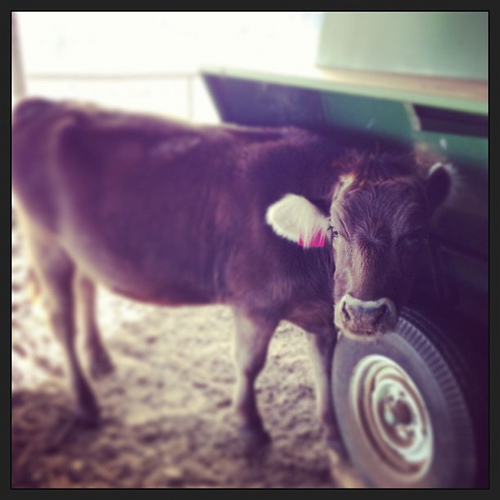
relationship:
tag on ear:
[297, 230, 326, 249] [267, 191, 333, 249]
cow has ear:
[11, 98, 455, 446] [267, 191, 333, 249]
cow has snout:
[11, 98, 455, 446] [330, 293, 399, 341]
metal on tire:
[347, 352, 434, 483] [332, 314, 489, 489]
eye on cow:
[330, 229, 340, 240] [11, 98, 455, 446]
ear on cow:
[424, 163, 459, 211] [11, 98, 455, 446]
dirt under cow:
[12, 236, 338, 489] [11, 98, 455, 446]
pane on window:
[13, 17, 25, 103] [12, 13, 320, 124]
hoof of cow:
[233, 418, 274, 447] [11, 98, 455, 446]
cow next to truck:
[11, 98, 455, 446] [195, 11, 490, 495]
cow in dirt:
[11, 98, 455, 446] [12, 236, 338, 489]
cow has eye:
[11, 98, 455, 446] [330, 229, 340, 240]